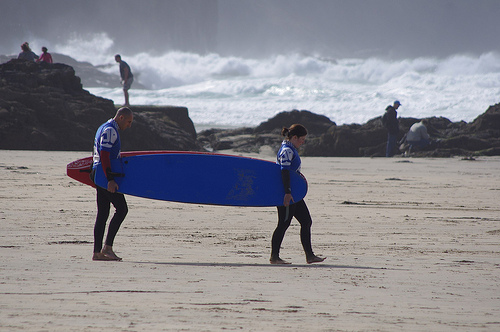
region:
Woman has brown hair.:
[273, 125, 346, 155]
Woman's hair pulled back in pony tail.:
[263, 121, 324, 146]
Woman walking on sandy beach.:
[253, 146, 354, 318]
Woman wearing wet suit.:
[266, 132, 328, 268]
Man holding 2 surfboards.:
[62, 103, 149, 272]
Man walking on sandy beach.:
[47, 148, 142, 275]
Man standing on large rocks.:
[101, 50, 143, 102]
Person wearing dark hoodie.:
[377, 102, 404, 132]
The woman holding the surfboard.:
[262, 106, 339, 261]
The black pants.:
[275, 199, 315, 254]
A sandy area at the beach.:
[350, 166, 486, 329]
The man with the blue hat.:
[378, 93, 404, 160]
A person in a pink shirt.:
[36, 45, 56, 65]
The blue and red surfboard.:
[65, 149, 307, 211]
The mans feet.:
[85, 237, 125, 280]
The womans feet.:
[261, 245, 330, 273]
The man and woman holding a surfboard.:
[55, 98, 342, 259]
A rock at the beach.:
[2, 66, 94, 150]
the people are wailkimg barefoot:
[46, 214, 351, 307]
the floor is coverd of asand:
[205, 262, 331, 331]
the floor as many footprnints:
[208, 257, 318, 331]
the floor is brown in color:
[201, 271, 325, 329]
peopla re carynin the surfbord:
[92, 112, 300, 264]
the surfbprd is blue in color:
[121, 151, 266, 235]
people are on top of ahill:
[21, 30, 137, 100]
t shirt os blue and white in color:
[48, 98, 123, 167]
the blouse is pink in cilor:
[31, 47, 56, 64]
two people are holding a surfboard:
[75, 100, 440, 314]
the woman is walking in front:
[260, 110, 347, 265]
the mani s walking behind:
[81, 93, 143, 238]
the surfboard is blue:
[93, 143, 407, 325]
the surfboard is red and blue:
[60, 150, 169, 247]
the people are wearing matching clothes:
[77, 120, 465, 330]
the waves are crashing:
[187, 59, 337, 173]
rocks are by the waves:
[284, 93, 488, 220]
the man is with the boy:
[374, 95, 483, 184]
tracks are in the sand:
[12, 160, 133, 328]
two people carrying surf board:
[62, 97, 332, 283]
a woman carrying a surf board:
[265, 107, 325, 281]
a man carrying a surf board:
[62, 91, 139, 269]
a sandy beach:
[377, 174, 481, 329]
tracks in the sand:
[26, 261, 414, 331]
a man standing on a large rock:
[106, 26, 151, 120]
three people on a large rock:
[13, 26, 60, 82]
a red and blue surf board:
[62, 156, 316, 204]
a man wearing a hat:
[386, 83, 406, 110]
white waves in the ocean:
[177, 43, 447, 101]